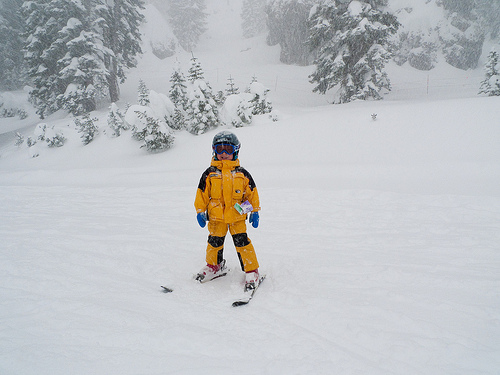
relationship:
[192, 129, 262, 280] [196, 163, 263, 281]
boy wears an orange jacket/pants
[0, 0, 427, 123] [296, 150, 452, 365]
trees covered with snow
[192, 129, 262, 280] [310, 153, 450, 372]
boy standing on snow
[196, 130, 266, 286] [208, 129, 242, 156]
boy wears a helmet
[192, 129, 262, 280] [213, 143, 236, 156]
boy wears blue goggles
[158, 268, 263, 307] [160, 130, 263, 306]
boy's skis on a boy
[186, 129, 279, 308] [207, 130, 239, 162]
boy with hat/ski goggles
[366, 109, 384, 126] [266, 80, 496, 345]
object in snow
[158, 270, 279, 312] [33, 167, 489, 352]
skis covered in snow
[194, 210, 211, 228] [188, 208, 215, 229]
boy's gloves on hand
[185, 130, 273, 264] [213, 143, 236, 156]
boy wearing blue goggles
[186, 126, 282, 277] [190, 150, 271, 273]
boy wearing snow suit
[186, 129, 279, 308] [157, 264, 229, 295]
boy wearing skis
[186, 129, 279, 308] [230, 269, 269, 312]
boy wearing skis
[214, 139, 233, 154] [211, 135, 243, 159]
lenses on goggles